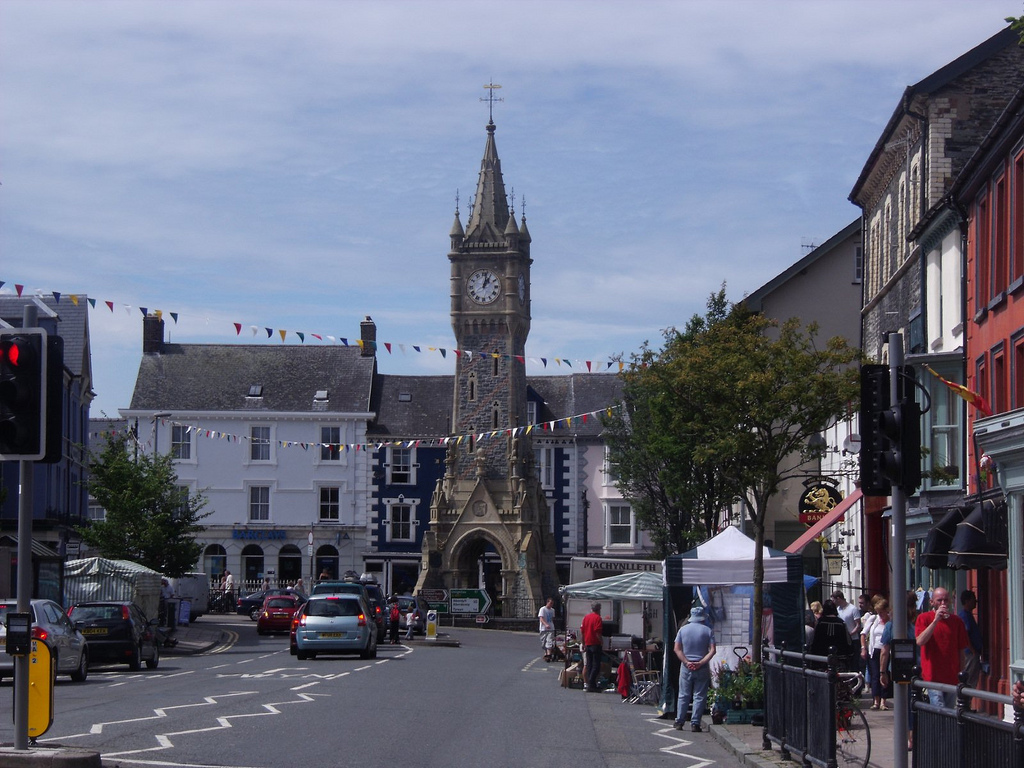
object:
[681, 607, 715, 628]
hat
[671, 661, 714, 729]
pants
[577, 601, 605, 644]
shirt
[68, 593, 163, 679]
station wagon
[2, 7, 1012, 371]
sky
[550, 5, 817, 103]
clouds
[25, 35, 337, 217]
cloud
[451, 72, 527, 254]
roof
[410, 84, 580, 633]
tower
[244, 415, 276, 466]
window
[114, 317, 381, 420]
roof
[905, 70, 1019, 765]
building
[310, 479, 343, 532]
window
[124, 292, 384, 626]
building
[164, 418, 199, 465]
window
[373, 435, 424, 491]
window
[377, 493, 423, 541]
window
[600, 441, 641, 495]
window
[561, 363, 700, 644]
building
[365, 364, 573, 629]
building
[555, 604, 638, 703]
man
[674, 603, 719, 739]
man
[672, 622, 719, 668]
blue shirt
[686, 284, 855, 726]
green tree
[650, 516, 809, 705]
white/blue tent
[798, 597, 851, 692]
people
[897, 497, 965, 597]
store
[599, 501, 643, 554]
window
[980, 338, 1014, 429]
window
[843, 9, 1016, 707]
building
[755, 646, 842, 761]
railing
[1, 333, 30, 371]
signal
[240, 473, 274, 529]
window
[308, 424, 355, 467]
window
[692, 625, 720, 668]
arms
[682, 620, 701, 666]
back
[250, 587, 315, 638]
red car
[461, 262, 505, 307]
white clock